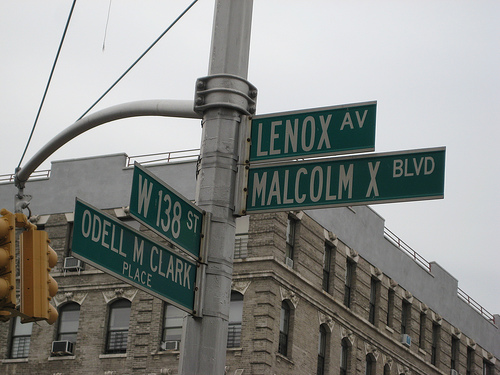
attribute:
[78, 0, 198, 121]
wire — electric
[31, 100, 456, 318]
signs — green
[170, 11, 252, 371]
pole — gray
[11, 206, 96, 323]
light — hanging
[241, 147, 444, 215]
sign — street, Malcolm X Boulevard, green, white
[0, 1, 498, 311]
sky — pale, blue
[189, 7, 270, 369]
post — gray, metal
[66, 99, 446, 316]
street signs — green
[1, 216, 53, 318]
light — traffic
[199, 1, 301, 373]
post — silver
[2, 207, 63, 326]
signal — traffic, yellow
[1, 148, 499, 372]
building — gray, stone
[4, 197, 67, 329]
light — street